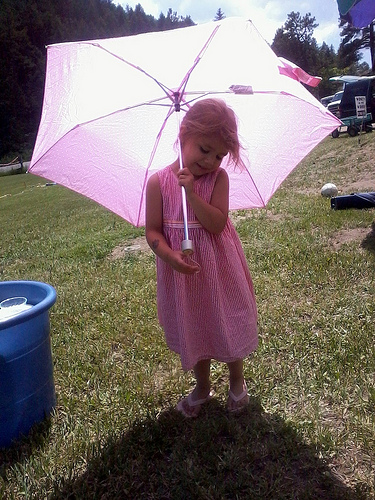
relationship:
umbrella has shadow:
[25, 14, 342, 226] [53, 392, 349, 489]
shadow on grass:
[53, 392, 349, 489] [1, 128, 374, 495]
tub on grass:
[0, 283, 57, 444] [1, 128, 374, 495]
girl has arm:
[147, 97, 254, 416] [143, 177, 174, 269]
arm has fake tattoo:
[143, 177, 174, 269] [148, 237, 160, 248]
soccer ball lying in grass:
[320, 182, 338, 200] [1, 128, 374, 495]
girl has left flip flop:
[147, 97, 254, 416] [222, 385, 252, 417]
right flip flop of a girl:
[173, 385, 211, 417] [147, 97, 254, 416]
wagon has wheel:
[332, 109, 373, 137] [347, 127, 357, 138]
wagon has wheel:
[330, 127, 341, 138] [365, 123, 374, 134]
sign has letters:
[352, 94, 368, 132] [354, 95, 367, 118]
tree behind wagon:
[336, 6, 374, 77] [332, 109, 373, 137]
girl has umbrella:
[147, 97, 254, 416] [25, 14, 342, 226]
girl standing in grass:
[147, 97, 254, 416] [1, 128, 374, 495]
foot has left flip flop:
[225, 379, 248, 410] [222, 385, 252, 417]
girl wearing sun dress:
[147, 97, 254, 416] [156, 162, 257, 362]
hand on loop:
[174, 249, 201, 280] [186, 249, 202, 275]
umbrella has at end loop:
[25, 14, 342, 226] [186, 249, 202, 275]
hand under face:
[175, 169, 196, 190] [184, 132, 222, 177]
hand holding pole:
[175, 169, 196, 190] [169, 103, 195, 249]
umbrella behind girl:
[25, 14, 342, 226] [147, 97, 254, 416]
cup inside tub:
[4, 294, 31, 317] [0, 283, 57, 444]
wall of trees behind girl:
[0, 2, 341, 170] [147, 97, 254, 416]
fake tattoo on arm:
[148, 237, 160, 248] [143, 177, 174, 269]